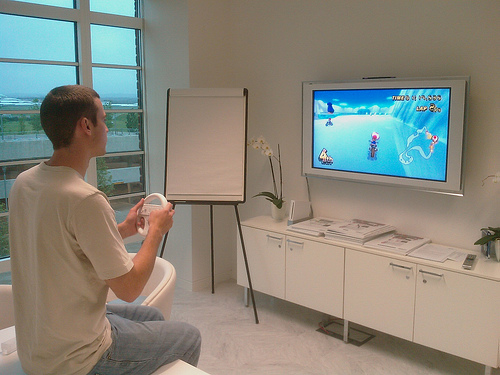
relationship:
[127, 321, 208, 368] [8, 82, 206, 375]
leg of a man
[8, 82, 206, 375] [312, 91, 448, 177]
man playing a game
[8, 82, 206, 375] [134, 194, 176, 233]
man holding game controller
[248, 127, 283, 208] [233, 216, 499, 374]
flowers on top of cabinet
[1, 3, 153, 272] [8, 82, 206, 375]
windows beside man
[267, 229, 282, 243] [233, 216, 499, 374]
handle on cabinet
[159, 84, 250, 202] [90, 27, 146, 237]
paper beside window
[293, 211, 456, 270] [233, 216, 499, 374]
papers on cabinet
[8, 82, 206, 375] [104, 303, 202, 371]
man wearing blue jeans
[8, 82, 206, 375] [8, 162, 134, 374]
man wearing shirt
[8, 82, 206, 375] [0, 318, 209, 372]
man sitting on desk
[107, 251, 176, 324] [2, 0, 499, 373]
chair in office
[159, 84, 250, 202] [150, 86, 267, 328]
paper on easel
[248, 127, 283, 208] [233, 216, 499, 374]
flowers on cabinet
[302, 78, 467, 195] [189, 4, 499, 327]
tv on wall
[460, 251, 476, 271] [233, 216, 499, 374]
remote control on cabinet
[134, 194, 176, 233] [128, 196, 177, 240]
game controller in hands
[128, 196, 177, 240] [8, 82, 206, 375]
hands of man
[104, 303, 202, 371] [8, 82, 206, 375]
blue jeans on a man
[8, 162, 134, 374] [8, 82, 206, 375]
shirt on a man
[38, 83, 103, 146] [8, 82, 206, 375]
hair on a man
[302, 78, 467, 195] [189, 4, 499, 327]
tv on a wall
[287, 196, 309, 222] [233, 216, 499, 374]
wii console on cabinet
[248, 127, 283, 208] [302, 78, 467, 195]
flowers by tv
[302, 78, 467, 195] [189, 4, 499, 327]
tv mounted on a wall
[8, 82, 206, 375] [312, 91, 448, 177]
man playing game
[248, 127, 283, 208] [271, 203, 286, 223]
flowers in vase